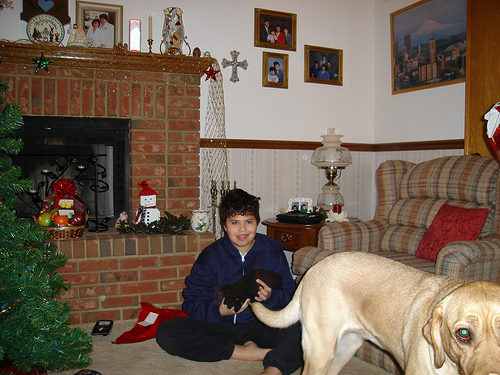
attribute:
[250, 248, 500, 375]
labrador — yellow, labrorador, brown, looking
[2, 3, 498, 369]
room — here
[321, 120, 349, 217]
lamp — here, pretty, cream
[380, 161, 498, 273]
chair — overstuffed, reclining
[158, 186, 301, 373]
boy — young, posing, smiling, sitting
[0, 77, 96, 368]
tree — decorationless, christmas, christmasy, articficial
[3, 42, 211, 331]
fireplace — large, here, bricks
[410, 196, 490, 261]
pillow — red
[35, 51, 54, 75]
star — green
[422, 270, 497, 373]
dog — cream, brown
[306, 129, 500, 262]
sofa — checkered